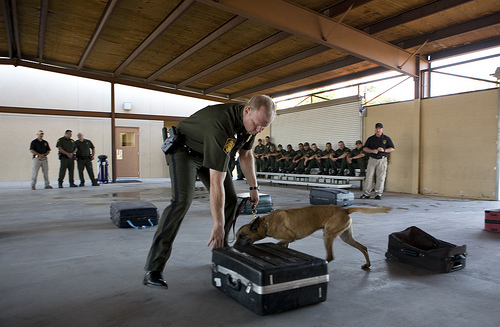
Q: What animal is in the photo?
A: Dog.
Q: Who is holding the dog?
A: Officer.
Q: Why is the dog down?
A: Smelling.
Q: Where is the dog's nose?
A: Suitcase.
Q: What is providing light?
A: Sun.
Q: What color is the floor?
A: Gray.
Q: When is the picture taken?
A: Daytime.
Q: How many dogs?
A: One.